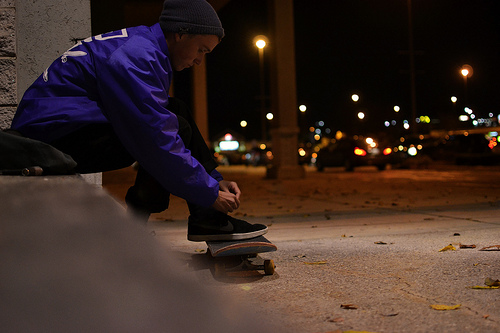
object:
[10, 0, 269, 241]
man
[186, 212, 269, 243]
shoe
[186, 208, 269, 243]
foot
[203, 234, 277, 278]
skateboard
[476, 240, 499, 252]
leaf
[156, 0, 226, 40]
hat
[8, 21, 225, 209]
jacket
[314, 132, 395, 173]
vehicle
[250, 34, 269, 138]
street light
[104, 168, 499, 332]
sidewalk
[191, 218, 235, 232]
logo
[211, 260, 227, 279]
wheel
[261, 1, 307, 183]
pillar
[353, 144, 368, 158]
tail light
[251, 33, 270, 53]
light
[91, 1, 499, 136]
sky